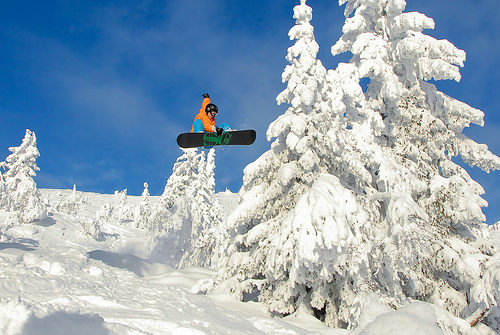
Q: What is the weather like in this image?
A: It is clear.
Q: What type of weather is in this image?
A: It is clear.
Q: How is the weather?
A: It is clear.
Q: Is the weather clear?
A: Yes, it is clear.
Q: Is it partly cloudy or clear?
A: It is clear.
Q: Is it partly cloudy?
A: No, it is clear.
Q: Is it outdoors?
A: Yes, it is outdoors.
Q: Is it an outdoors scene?
A: Yes, it is outdoors.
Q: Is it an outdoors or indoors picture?
A: It is outdoors.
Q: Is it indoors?
A: No, it is outdoors.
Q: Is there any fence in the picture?
A: No, there are no fences.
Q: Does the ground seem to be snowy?
A: Yes, the ground is snowy.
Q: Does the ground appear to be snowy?
A: Yes, the ground is snowy.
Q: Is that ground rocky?
A: No, the ground is snowy.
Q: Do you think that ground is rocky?
A: No, the ground is snowy.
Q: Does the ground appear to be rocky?
A: No, the ground is snowy.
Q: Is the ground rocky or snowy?
A: The ground is snowy.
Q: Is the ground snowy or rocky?
A: The ground is snowy.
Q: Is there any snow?
A: Yes, there is snow.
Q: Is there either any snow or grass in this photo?
A: Yes, there is snow.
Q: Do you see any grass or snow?
A: Yes, there is snow.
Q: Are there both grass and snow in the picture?
A: No, there is snow but no grass.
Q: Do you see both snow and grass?
A: No, there is snow but no grass.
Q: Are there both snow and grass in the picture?
A: No, there is snow but no grass.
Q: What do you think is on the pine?
A: The snow is on the pine.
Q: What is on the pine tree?
A: The snow is on the pine.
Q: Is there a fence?
A: No, there are no fences.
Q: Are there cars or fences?
A: No, there are no fences or cars.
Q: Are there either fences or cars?
A: No, there are no fences or cars.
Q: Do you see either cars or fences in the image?
A: No, there are no fences or cars.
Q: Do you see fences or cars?
A: No, there are no fences or cars.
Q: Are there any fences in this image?
A: No, there are no fences.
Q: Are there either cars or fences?
A: No, there are no fences or cars.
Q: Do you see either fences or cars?
A: No, there are no fences or cars.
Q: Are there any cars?
A: No, there are no cars.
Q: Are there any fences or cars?
A: No, there are no cars or fences.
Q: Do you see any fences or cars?
A: No, there are no fences or cars.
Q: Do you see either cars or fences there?
A: No, there are no fences or cars.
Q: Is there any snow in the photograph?
A: Yes, there is snow.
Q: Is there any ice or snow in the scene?
A: Yes, there is snow.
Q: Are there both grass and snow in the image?
A: No, there is snow but no grass.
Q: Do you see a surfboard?
A: No, there are no surfboards.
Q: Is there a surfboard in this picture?
A: No, there are no surfboards.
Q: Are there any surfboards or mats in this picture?
A: No, there are no surfboards or mats.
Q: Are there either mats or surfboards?
A: No, there are no surfboards or mats.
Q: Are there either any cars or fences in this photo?
A: No, there are no fences or cars.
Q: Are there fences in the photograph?
A: No, there are no fences.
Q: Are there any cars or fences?
A: No, there are no fences or cars.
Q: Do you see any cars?
A: No, there are no cars.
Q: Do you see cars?
A: No, there are no cars.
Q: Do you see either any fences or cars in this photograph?
A: No, there are no cars or fences.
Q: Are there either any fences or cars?
A: No, there are no cars or fences.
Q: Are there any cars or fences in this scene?
A: No, there are no cars or fences.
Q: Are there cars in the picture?
A: No, there are no cars.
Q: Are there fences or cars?
A: No, there are no cars or fences.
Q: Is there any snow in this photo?
A: Yes, there is snow.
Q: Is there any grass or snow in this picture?
A: Yes, there is snow.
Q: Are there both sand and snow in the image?
A: No, there is snow but no sand.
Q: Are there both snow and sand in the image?
A: No, there is snow but no sand.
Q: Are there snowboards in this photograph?
A: Yes, there is a snowboard.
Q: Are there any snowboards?
A: Yes, there is a snowboard.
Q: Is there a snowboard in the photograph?
A: Yes, there is a snowboard.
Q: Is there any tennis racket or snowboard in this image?
A: Yes, there is a snowboard.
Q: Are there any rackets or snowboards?
A: Yes, there is a snowboard.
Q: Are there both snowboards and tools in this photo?
A: No, there is a snowboard but no tools.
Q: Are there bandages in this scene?
A: No, there are no bandages.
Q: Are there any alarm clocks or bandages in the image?
A: No, there are no bandages or alarm clocks.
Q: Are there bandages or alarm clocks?
A: No, there are no bandages or alarm clocks.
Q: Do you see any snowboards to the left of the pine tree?
A: Yes, there is a snowboard to the left of the pine tree.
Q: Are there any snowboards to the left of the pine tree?
A: Yes, there is a snowboard to the left of the pine tree.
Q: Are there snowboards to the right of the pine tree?
A: No, the snowboard is to the left of the pine tree.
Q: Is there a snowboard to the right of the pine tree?
A: No, the snowboard is to the left of the pine tree.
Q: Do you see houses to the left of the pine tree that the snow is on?
A: No, there is a snowboard to the left of the pine.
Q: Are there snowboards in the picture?
A: Yes, there is a snowboard.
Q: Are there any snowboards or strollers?
A: Yes, there is a snowboard.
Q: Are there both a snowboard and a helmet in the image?
A: Yes, there are both a snowboard and a helmet.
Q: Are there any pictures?
A: No, there are no pictures.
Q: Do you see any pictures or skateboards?
A: No, there are no pictures or skateboards.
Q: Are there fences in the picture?
A: No, there are no fences.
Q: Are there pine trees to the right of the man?
A: Yes, there is a pine tree to the right of the man.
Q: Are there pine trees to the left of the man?
A: No, the pine tree is to the right of the man.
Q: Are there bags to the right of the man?
A: No, there is a pine tree to the right of the man.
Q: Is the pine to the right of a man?
A: Yes, the pine is to the right of a man.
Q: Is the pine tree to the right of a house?
A: No, the pine tree is to the right of a man.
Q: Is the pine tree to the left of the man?
A: No, the pine tree is to the right of the man.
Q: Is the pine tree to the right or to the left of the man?
A: The pine tree is to the right of the man.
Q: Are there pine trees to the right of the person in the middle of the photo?
A: Yes, there is a pine tree to the right of the person.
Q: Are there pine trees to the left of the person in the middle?
A: No, the pine tree is to the right of the person.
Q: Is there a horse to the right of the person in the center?
A: No, there is a pine tree to the right of the person.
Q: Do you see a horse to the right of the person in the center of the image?
A: No, there is a pine tree to the right of the person.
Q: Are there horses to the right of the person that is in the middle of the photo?
A: No, there is a pine tree to the right of the person.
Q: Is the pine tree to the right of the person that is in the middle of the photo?
A: Yes, the pine tree is to the right of the person.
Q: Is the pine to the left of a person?
A: No, the pine is to the right of a person.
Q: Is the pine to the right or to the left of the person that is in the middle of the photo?
A: The pine is to the right of the person.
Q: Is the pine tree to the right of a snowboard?
A: Yes, the pine tree is to the right of a snowboard.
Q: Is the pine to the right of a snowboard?
A: Yes, the pine is to the right of a snowboard.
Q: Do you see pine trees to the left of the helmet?
A: No, the pine tree is to the right of the helmet.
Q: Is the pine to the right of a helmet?
A: Yes, the pine is to the right of a helmet.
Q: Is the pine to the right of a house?
A: No, the pine is to the right of a helmet.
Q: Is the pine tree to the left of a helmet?
A: No, the pine tree is to the right of a helmet.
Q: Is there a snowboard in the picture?
A: Yes, there is a snowboard.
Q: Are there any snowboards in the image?
A: Yes, there is a snowboard.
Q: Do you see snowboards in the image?
A: Yes, there is a snowboard.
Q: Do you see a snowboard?
A: Yes, there is a snowboard.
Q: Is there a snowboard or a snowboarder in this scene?
A: Yes, there is a snowboard.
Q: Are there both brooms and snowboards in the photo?
A: No, there is a snowboard but no brooms.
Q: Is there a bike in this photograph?
A: No, there are no bikes.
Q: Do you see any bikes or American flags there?
A: No, there are no bikes or American flags.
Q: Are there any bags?
A: No, there are no bags.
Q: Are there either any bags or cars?
A: No, there are no bags or cars.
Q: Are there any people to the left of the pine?
A: Yes, there is a person to the left of the pine.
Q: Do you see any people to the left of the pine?
A: Yes, there is a person to the left of the pine.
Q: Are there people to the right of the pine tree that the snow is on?
A: No, the person is to the left of the pine.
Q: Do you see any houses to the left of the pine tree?
A: No, there is a person to the left of the pine tree.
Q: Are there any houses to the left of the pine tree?
A: No, there is a person to the left of the pine tree.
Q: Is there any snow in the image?
A: Yes, there is snow.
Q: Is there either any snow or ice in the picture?
A: Yes, there is snow.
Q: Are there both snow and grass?
A: No, there is snow but no grass.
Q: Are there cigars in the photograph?
A: No, there are no cigars.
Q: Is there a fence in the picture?
A: No, there are no fences.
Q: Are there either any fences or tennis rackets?
A: No, there are no fences or tennis rackets.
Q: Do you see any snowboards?
A: Yes, there is a snowboard.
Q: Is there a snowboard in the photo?
A: Yes, there is a snowboard.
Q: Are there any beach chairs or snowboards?
A: Yes, there is a snowboard.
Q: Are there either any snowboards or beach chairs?
A: Yes, there is a snowboard.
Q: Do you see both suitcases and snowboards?
A: No, there is a snowboard but no suitcases.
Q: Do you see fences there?
A: No, there are no fences.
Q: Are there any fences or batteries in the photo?
A: No, there are no fences or batteries.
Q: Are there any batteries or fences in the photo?
A: No, there are no fences or batteries.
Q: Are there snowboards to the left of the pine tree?
A: Yes, there is a snowboard to the left of the pine tree.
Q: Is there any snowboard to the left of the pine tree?
A: Yes, there is a snowboard to the left of the pine tree.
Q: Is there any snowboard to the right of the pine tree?
A: No, the snowboard is to the left of the pine tree.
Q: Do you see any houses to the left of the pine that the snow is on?
A: No, there is a snowboard to the left of the pine.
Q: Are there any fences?
A: No, there are no fences.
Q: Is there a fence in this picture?
A: No, there are no fences.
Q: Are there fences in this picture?
A: No, there are no fences.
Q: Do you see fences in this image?
A: No, there are no fences.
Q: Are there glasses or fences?
A: No, there are no fences or glasses.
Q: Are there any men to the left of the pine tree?
A: Yes, there is a man to the left of the pine tree.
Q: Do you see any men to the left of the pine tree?
A: Yes, there is a man to the left of the pine tree.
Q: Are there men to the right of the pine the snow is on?
A: No, the man is to the left of the pine tree.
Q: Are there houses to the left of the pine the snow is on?
A: No, there is a man to the left of the pine.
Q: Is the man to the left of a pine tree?
A: Yes, the man is to the left of a pine tree.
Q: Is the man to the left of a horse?
A: No, the man is to the left of a pine tree.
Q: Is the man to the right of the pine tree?
A: No, the man is to the left of the pine tree.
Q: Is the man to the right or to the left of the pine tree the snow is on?
A: The man is to the left of the pine tree.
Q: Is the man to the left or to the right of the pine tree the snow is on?
A: The man is to the left of the pine tree.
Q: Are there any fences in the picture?
A: No, there are no fences.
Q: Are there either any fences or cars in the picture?
A: No, there are no fences or cars.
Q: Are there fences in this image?
A: No, there are no fences.